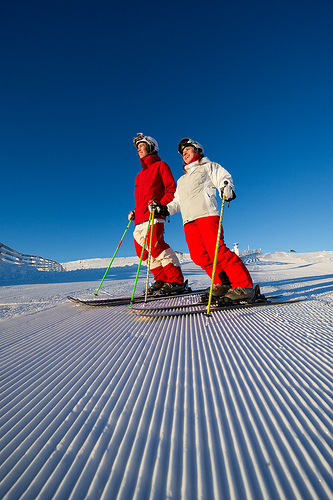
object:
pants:
[192, 220, 265, 307]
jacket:
[118, 156, 233, 231]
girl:
[168, 132, 210, 214]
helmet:
[118, 126, 212, 173]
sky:
[168, 29, 283, 113]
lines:
[72, 266, 99, 452]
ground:
[113, 332, 254, 456]